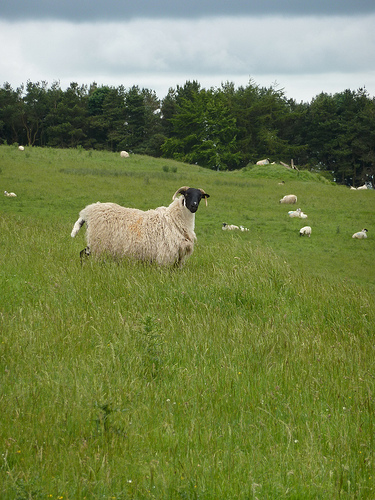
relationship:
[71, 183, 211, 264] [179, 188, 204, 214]
sheep has face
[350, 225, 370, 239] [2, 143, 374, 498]
sheep lying in grass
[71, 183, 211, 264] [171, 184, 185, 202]
sheep has horn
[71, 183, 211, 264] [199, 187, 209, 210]
sheep has horn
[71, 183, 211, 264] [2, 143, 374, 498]
sheep standing in grass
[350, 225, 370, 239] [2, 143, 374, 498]
sheep laying in grass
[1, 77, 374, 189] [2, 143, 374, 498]
trees behind grass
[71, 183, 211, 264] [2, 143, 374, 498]
sheep in grass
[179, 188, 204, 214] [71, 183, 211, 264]
face of sheep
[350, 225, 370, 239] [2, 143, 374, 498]
sheep in grass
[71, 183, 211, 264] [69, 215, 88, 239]
sheep has tail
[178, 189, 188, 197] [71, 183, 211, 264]
ear of sheep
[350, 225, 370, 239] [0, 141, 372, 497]
sheep on hill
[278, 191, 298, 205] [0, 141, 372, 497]
sheep on hill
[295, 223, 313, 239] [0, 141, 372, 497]
sheep on hill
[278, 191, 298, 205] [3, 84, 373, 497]
sheep on hill